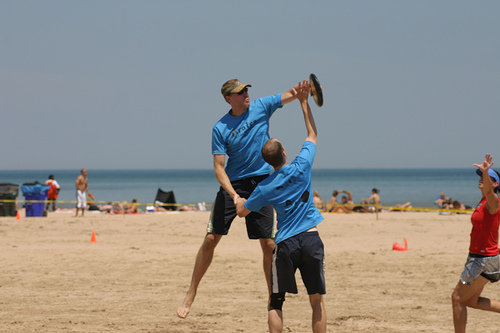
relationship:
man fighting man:
[176, 78, 311, 318] [235, 79, 328, 332]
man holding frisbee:
[176, 78, 311, 318] [308, 74, 323, 108]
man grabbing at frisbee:
[235, 79, 328, 332] [308, 74, 323, 108]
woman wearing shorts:
[451, 153, 500, 331] [461, 253, 499, 285]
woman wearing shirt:
[451, 153, 500, 331] [468, 196, 499, 256]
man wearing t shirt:
[176, 78, 311, 318] [212, 93, 284, 181]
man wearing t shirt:
[235, 79, 328, 332] [244, 139, 324, 243]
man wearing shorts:
[176, 78, 311, 318] [207, 175, 278, 239]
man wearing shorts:
[235, 79, 328, 332] [270, 231, 326, 296]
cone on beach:
[392, 242, 408, 252] [1, 208, 499, 331]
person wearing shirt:
[43, 174, 60, 212] [45, 179, 61, 199]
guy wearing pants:
[76, 169, 93, 215] [76, 189, 88, 210]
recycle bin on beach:
[20, 181, 53, 219] [1, 208, 499, 331]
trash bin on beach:
[1, 181, 22, 219] [1, 208, 499, 331]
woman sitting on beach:
[361, 188, 382, 207] [1, 208, 499, 331]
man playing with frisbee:
[176, 78, 311, 318] [308, 74, 323, 108]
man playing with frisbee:
[235, 79, 328, 332] [308, 74, 323, 108]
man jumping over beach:
[176, 78, 311, 318] [1, 208, 499, 331]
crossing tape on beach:
[0, 197, 477, 216] [1, 208, 499, 331]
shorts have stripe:
[270, 231, 326, 296] [271, 243, 282, 294]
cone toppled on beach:
[392, 242, 408, 252] [1, 208, 499, 331]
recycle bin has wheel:
[20, 181, 53, 219] [41, 208, 48, 217]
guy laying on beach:
[341, 189, 384, 214] [1, 208, 499, 331]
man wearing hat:
[176, 78, 311, 318] [221, 79, 253, 96]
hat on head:
[221, 79, 253, 96] [224, 86, 252, 109]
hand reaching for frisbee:
[292, 80, 313, 101] [308, 74, 323, 108]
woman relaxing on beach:
[361, 188, 382, 207] [1, 208, 499, 331]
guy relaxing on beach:
[341, 189, 384, 214] [1, 208, 499, 331]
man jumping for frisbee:
[176, 78, 311, 318] [308, 74, 323, 108]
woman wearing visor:
[451, 153, 500, 331] [476, 167, 499, 181]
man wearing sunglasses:
[176, 78, 311, 318] [228, 86, 250, 97]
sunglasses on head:
[228, 86, 250, 97] [224, 86, 252, 109]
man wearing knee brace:
[235, 79, 328, 332] [268, 291, 287, 313]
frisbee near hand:
[308, 74, 323, 108] [292, 80, 313, 101]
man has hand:
[235, 79, 328, 332] [292, 80, 313, 101]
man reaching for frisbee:
[176, 78, 311, 318] [308, 74, 323, 108]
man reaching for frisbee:
[235, 79, 328, 332] [308, 74, 323, 108]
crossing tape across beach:
[0, 197, 477, 216] [1, 208, 499, 331]